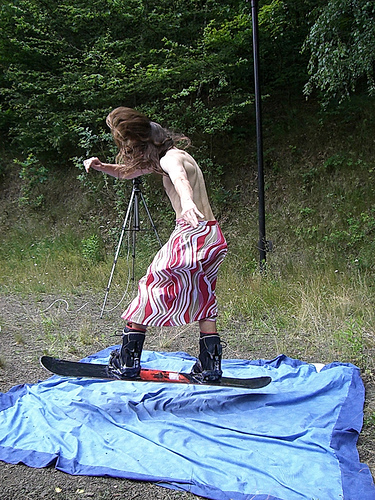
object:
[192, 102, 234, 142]
branch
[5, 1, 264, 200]
tree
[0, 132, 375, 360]
gras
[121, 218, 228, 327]
dress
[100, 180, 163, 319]
tripod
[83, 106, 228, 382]
man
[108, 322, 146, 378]
boots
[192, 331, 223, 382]
boots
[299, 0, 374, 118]
tree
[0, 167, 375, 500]
ground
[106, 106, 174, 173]
mask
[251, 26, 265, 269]
pole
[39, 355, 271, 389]
skate board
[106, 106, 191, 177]
hair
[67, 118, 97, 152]
tree branch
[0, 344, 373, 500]
blanket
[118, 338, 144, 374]
black snap